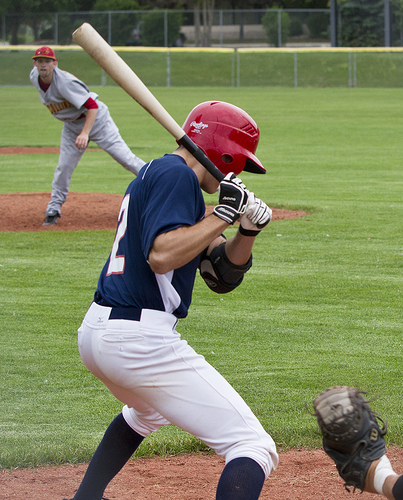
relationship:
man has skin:
[74, 101, 276, 500] [149, 147, 256, 275]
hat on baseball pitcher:
[26, 45, 57, 58] [30, 44, 112, 193]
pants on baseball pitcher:
[40, 110, 120, 224] [26, 46, 106, 227]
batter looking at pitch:
[78, 94, 277, 500] [28, 80, 82, 150]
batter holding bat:
[78, 94, 277, 500] [64, 20, 189, 133]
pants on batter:
[75, 301, 241, 451] [78, 94, 277, 500]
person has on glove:
[78, 99, 298, 500] [214, 172, 245, 219]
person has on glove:
[78, 99, 298, 500] [243, 183, 275, 227]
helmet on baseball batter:
[179, 100, 265, 178] [83, 98, 259, 466]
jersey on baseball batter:
[99, 170, 197, 318] [83, 98, 259, 466]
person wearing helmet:
[78, 99, 298, 500] [181, 98, 260, 181]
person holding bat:
[78, 99, 298, 500] [66, 21, 160, 119]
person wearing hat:
[23, 46, 148, 228] [28, 43, 59, 59]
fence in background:
[137, 48, 375, 91] [18, 14, 383, 77]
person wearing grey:
[23, 46, 148, 228] [52, 85, 77, 95]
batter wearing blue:
[91, 101, 260, 474] [151, 177, 188, 207]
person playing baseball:
[116, 99, 297, 496] [58, 13, 189, 150]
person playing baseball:
[23, 46, 137, 196] [58, 13, 189, 150]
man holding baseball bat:
[74, 101, 270, 432] [68, 18, 216, 175]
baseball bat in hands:
[68, 18, 216, 175] [215, 171, 275, 228]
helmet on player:
[179, 100, 265, 178] [98, 100, 273, 439]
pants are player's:
[75, 301, 241, 451] [80, 106, 308, 484]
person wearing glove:
[78, 99, 298, 500] [215, 169, 247, 223]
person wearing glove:
[78, 99, 298, 500] [240, 189, 273, 235]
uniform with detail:
[29, 66, 141, 211] [43, 98, 74, 113]